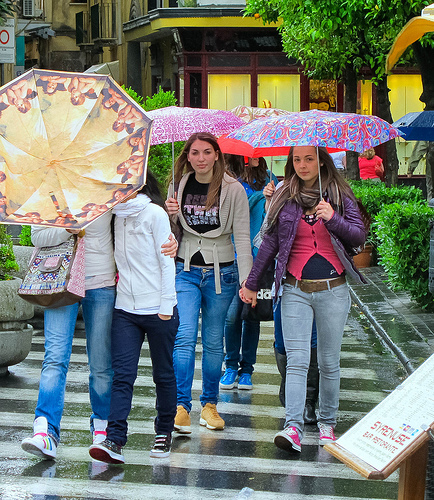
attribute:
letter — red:
[400, 434, 413, 444]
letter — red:
[371, 417, 383, 426]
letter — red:
[379, 424, 387, 435]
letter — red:
[382, 424, 391, 438]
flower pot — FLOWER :
[0, 273, 35, 367]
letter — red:
[400, 435, 411, 445]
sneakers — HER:
[75, 430, 201, 479]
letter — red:
[367, 414, 412, 452]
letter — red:
[393, 429, 405, 445]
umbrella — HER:
[228, 105, 409, 155]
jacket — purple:
[240, 174, 366, 295]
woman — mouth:
[157, 124, 263, 442]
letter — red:
[381, 440, 389, 449]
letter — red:
[396, 432, 405, 446]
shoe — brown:
[172, 402, 194, 442]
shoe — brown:
[198, 399, 227, 432]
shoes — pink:
[270, 416, 334, 461]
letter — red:
[0, 29, 8, 45]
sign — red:
[1, 17, 18, 63]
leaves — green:
[371, 204, 433, 290]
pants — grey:
[278, 275, 352, 429]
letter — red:
[370, 416, 388, 439]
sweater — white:
[107, 195, 168, 313]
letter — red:
[351, 410, 414, 462]